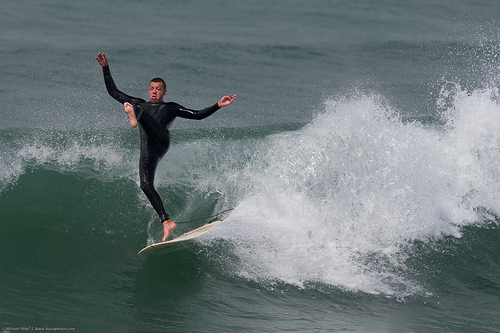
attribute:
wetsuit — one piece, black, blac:
[103, 65, 223, 220]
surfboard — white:
[138, 218, 222, 256]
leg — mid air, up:
[124, 101, 169, 150]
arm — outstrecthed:
[102, 65, 145, 105]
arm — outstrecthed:
[172, 102, 220, 119]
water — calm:
[1, 1, 500, 332]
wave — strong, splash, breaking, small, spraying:
[0, 2, 499, 306]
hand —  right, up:
[94, 51, 110, 66]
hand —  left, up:
[217, 93, 236, 107]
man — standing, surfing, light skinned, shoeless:
[95, 50, 239, 242]